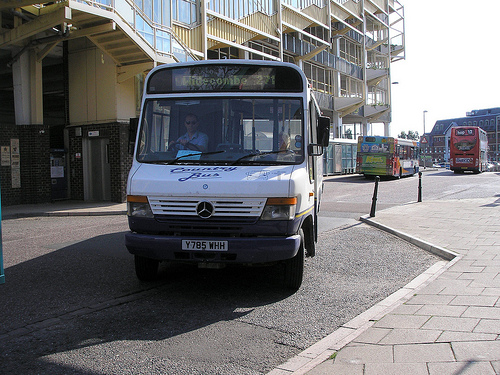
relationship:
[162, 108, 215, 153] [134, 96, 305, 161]
driver visible through windshield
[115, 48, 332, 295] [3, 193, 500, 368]
bus on street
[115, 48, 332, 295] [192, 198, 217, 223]
bus has sign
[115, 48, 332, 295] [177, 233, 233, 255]
bus has plate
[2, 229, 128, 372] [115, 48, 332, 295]
shadow of bus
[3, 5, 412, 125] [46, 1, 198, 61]
building has stair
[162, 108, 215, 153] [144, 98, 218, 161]
driver on right side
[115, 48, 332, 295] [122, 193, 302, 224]
bus has headlight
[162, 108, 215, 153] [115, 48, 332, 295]
man driving vehicle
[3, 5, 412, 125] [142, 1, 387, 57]
building has windows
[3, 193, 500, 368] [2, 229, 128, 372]
road has shadows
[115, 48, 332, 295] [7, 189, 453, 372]
bus stopped on road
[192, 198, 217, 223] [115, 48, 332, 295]
logo on front van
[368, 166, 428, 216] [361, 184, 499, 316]
posts on curb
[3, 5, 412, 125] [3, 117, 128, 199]
building has red bricks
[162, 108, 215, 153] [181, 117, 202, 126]
driver wearing sunglasses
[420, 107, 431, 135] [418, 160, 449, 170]
post on curb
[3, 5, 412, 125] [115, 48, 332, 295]
building behind bus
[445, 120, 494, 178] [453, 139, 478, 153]
bus has advertisement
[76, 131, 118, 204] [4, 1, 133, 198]
entrance to building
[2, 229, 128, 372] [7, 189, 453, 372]
shadow on road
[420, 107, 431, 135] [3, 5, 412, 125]
pole near building